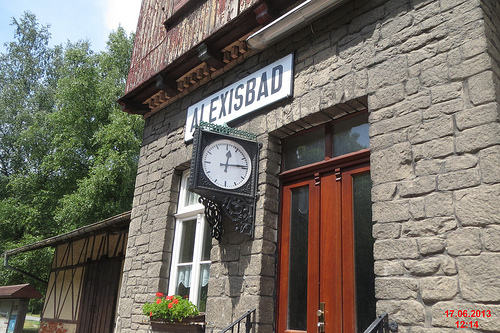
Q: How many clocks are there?
A: One.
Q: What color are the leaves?
A: Green.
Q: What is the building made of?
A: Stone.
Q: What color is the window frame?
A: White.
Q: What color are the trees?
A: Green.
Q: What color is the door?
A: Brown.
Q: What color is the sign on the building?
A: White and black.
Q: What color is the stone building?
A: Gray.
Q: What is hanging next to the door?
A: A clock.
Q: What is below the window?
A: Flowers.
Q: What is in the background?
A: Trees.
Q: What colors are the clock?
A: Black and white.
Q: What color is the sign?
A: White.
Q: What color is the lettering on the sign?
A: Black.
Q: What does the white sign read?
A: Alexisbad.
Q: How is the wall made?
A: Of stone.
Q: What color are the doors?
A: Brown.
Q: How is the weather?
A: Sunny.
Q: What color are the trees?
A: Green.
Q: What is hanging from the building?
A: A clock.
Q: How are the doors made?
A: Of wood.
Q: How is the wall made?
A: Of stone.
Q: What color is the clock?
A: White and black.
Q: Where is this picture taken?
A: ALexisbad.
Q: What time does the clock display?
A: 12:15.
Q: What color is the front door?
A: It is brown.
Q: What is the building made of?
A: It's made of bricks.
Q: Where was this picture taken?
A: On the street.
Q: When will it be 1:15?
A: In 1 hour.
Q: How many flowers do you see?
A: 6 flowers.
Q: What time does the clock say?
A: 12:15.